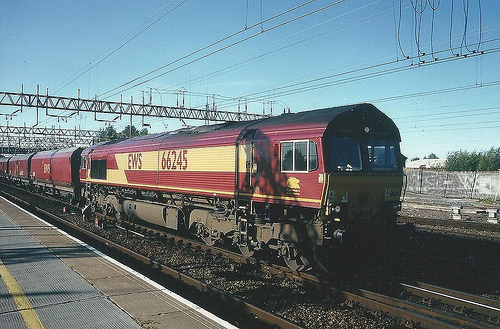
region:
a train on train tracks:
[9, 109, 424, 287]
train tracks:
[368, 269, 486, 326]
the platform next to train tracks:
[12, 203, 180, 322]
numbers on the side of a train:
[155, 144, 199, 183]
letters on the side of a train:
[120, 147, 147, 177]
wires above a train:
[36, 57, 256, 122]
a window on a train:
[272, 134, 333, 183]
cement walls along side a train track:
[415, 152, 495, 199]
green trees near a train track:
[445, 142, 498, 171]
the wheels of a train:
[227, 217, 327, 278]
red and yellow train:
[17, 144, 381, 229]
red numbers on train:
[111, 144, 245, 189]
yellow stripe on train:
[94, 151, 246, 180]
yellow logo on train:
[277, 171, 310, 198]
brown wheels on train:
[100, 183, 301, 263]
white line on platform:
[23, 204, 188, 327]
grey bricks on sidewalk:
[0, 254, 120, 317]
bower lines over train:
[15, 88, 253, 131]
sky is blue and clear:
[115, 13, 234, 81]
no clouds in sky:
[53, 23, 185, 88]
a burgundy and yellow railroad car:
[76, 100, 411, 271]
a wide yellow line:
[0, 257, 42, 322]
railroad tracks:
[0, 180, 425, 325]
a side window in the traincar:
[275, 136, 315, 172]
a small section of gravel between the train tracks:
[290, 305, 350, 320]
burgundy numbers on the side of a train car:
[157, 150, 187, 170]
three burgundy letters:
[125, 153, 143, 169]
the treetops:
[438, 148, 498, 169]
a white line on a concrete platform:
[0, 194, 235, 327]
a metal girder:
[0, 93, 278, 120]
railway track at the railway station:
[196, 255, 488, 320]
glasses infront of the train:
[326, 120, 406, 185]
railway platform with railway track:
[8, 204, 126, 327]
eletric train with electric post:
[41, 92, 303, 167]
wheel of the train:
[187, 209, 337, 269]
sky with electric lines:
[68, 10, 453, 95]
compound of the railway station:
[426, 172, 497, 212]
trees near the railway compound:
[446, 155, 498, 169]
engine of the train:
[271, 99, 408, 269]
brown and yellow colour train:
[29, 110, 379, 204]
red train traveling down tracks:
[6, 110, 393, 272]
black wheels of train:
[7, 177, 299, 272]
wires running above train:
[42, 6, 494, 98]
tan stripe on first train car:
[97, 143, 245, 189]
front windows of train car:
[322, 144, 394, 176]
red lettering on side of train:
[122, 149, 188, 176]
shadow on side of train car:
[224, 129, 290, 224]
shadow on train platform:
[2, 219, 112, 309]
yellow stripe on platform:
[5, 259, 35, 324]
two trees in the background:
[434, 145, 499, 172]